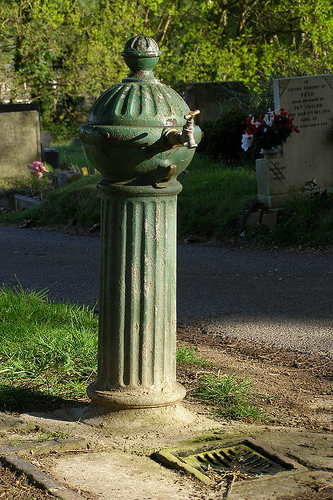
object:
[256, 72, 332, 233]
grave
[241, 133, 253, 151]
flower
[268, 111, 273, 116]
flower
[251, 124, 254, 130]
flower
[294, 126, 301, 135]
flower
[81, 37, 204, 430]
monument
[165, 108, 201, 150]
spout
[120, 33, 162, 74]
structure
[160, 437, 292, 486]
drain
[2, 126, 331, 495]
ground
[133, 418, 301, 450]
dirt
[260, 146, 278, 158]
vase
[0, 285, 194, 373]
grass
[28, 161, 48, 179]
flower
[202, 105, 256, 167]
bush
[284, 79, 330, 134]
epitaph